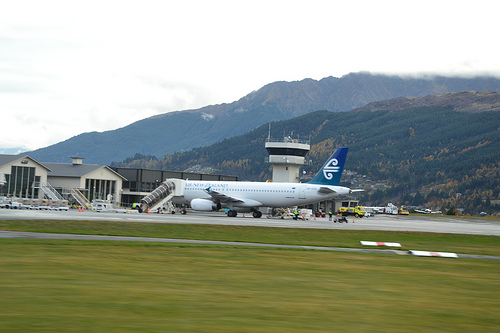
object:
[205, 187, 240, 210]
wing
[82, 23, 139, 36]
white clouds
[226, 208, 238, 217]
wheels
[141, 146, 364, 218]
plane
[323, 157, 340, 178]
design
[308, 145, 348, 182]
tail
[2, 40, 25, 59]
clouds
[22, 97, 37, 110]
cloud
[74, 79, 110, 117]
cloud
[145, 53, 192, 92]
cloud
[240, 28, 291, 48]
cloud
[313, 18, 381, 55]
cloud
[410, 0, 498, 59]
sky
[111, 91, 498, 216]
mountain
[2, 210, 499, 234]
tarmac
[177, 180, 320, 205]
side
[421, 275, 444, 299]
garden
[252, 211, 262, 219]
wheel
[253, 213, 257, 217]
part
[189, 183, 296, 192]
windows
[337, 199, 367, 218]
truck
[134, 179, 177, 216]
stairway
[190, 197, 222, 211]
engine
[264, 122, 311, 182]
control tower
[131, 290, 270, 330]
ground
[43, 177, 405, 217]
cones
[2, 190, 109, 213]
vehicles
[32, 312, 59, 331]
grass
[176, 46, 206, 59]
clouds